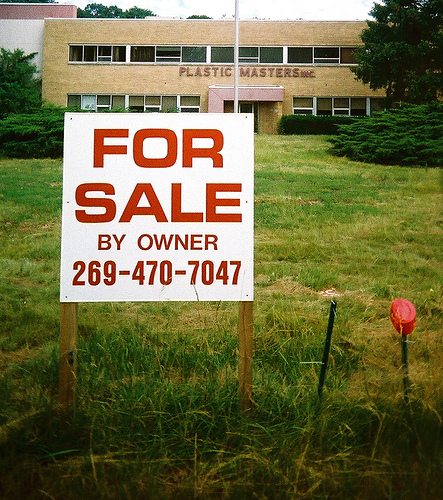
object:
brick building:
[37, 17, 442, 137]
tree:
[347, 0, 442, 111]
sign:
[60, 112, 254, 302]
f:
[94, 129, 128, 168]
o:
[133, 129, 177, 168]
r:
[183, 129, 223, 168]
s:
[76, 183, 116, 222]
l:
[172, 183, 204, 222]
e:
[207, 183, 243, 223]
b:
[98, 234, 112, 251]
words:
[179, 66, 235, 81]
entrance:
[237, 101, 262, 132]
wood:
[239, 300, 253, 419]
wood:
[60, 302, 79, 407]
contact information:
[72, 261, 241, 286]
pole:
[232, 0, 240, 112]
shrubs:
[0, 103, 64, 161]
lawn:
[1, 129, 441, 499]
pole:
[318, 298, 339, 395]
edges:
[59, 112, 179, 119]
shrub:
[278, 114, 358, 137]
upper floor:
[42, 17, 443, 96]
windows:
[312, 47, 340, 67]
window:
[68, 45, 84, 64]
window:
[83, 46, 97, 62]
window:
[111, 47, 125, 63]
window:
[131, 47, 156, 64]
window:
[182, 47, 207, 63]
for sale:
[76, 129, 242, 221]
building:
[0, 1, 77, 78]